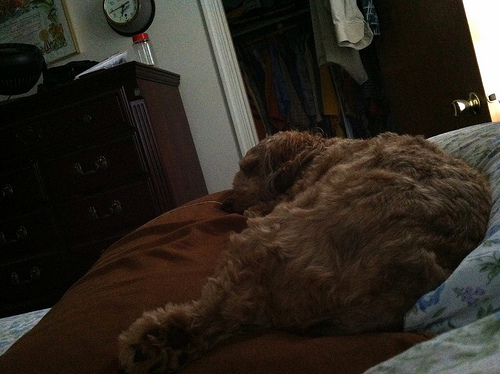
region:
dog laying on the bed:
[116, 127, 488, 369]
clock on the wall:
[90, 2, 162, 38]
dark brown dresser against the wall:
[5, 56, 208, 310]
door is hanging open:
[359, 6, 499, 142]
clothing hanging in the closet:
[244, 31, 364, 127]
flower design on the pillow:
[389, 113, 499, 335]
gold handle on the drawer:
[69, 154, 111, 182]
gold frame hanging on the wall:
[4, 2, 86, 73]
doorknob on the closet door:
[449, 88, 477, 118]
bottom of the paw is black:
[100, 303, 226, 373]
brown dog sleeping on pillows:
[219, 127, 491, 337]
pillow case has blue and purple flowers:
[418, 285, 490, 330]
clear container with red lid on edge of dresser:
[127, 33, 157, 73]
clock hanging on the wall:
[100, 0, 158, 34]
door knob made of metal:
[449, 91, 481, 120]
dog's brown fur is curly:
[265, 134, 340, 178]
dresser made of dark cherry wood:
[3, 90, 178, 204]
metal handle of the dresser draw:
[65, 152, 118, 184]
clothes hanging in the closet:
[240, 30, 376, 122]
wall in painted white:
[177, 34, 234, 108]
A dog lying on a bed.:
[111, 120, 494, 372]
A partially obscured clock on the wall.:
[103, 0, 160, 40]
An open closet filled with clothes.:
[215, 0, 497, 161]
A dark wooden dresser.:
[0, 59, 211, 319]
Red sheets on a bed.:
[0, 190, 428, 371]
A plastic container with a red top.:
[130, 31, 162, 71]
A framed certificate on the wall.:
[0, 0, 87, 70]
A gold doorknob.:
[447, 88, 490, 127]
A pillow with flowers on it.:
[403, 116, 498, 336]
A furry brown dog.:
[113, 127, 490, 372]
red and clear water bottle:
[131, 33, 156, 65]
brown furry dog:
[143, 133, 484, 366]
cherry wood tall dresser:
[6, 71, 192, 311]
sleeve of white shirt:
[330, 0, 370, 50]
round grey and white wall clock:
[101, 1, 159, 32]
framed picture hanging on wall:
[3, 0, 81, 57]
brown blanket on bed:
[13, 210, 399, 372]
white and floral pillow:
[411, 128, 497, 333]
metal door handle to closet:
[450, 93, 485, 116]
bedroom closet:
[215, 0, 434, 140]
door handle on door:
[448, 90, 483, 118]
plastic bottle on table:
[132, 33, 157, 68]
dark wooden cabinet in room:
[0, 59, 209, 294]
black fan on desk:
[0, 42, 46, 97]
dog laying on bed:
[121, 129, 488, 369]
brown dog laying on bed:
[115, 131, 490, 366]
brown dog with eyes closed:
[117, 123, 489, 366]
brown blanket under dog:
[3, 190, 417, 371]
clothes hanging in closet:
[245, 28, 369, 135]